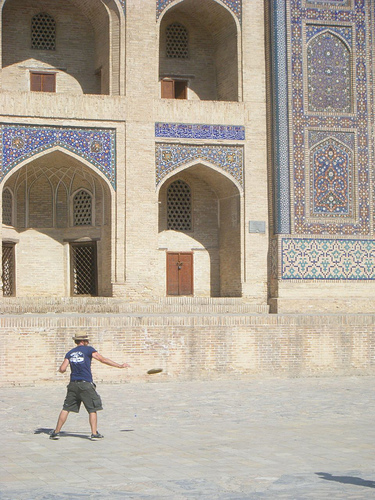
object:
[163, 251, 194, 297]
brown door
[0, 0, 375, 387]
beige building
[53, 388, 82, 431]
leg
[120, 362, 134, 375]
hand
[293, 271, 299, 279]
design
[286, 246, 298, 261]
design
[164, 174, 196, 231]
window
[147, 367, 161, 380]
frisbee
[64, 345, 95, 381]
shirt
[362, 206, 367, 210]
design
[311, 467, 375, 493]
shadow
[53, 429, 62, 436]
foot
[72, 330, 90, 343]
hat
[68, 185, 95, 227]
window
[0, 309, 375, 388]
wall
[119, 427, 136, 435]
shadow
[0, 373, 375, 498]
ground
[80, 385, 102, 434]
leg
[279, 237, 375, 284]
colorful tiled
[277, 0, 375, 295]
wall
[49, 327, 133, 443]
person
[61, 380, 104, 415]
green pants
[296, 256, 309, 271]
design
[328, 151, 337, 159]
design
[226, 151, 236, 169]
design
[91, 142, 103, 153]
design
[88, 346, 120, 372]
arm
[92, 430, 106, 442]
shoe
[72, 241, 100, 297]
lattice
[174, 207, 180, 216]
holes